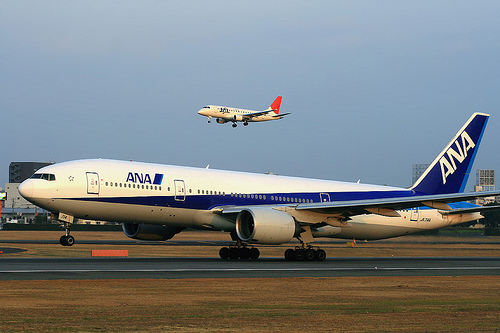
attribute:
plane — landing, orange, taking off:
[200, 100, 287, 128]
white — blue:
[35, 109, 499, 254]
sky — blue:
[28, 27, 442, 85]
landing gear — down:
[197, 224, 382, 265]